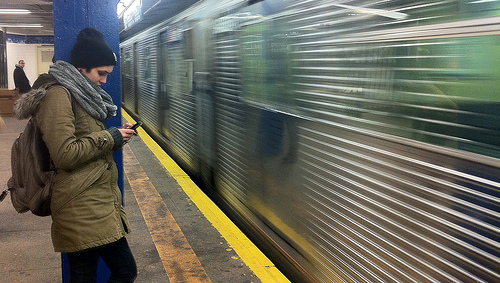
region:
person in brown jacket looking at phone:
[30, 23, 141, 279]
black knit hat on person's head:
[65, 25, 120, 67]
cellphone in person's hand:
[125, 115, 140, 130]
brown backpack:
[5, 120, 55, 216]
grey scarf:
[45, 60, 120, 120]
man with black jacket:
[10, 60, 30, 90]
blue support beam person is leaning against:
[50, 0, 115, 280]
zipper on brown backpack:
[0, 185, 10, 202]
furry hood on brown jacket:
[10, 72, 50, 117]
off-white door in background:
[35, 41, 55, 77]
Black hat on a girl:
[70, 26, 115, 66]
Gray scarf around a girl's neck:
[53, 72, 120, 109]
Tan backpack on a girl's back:
[6, 120, 58, 212]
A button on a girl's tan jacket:
[98, 136, 109, 144]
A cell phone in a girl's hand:
[129, 120, 141, 129]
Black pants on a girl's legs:
[64, 246, 138, 282]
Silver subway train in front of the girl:
[118, 11, 496, 281]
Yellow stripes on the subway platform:
[149, 175, 236, 278]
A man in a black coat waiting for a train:
[12, 56, 36, 93]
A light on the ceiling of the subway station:
[1, 4, 34, 18]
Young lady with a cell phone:
[15, 24, 150, 280]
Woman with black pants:
[7, 25, 156, 279]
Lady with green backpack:
[8, 24, 155, 281]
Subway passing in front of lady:
[123, 5, 499, 269]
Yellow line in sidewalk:
[121, 100, 274, 280]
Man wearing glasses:
[8, 52, 33, 97]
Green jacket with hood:
[13, 71, 133, 243]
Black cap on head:
[65, 23, 127, 65]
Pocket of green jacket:
[66, 161, 122, 223]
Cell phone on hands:
[113, 120, 147, 140]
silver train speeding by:
[299, 49, 484, 257]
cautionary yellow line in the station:
[139, 125, 278, 281]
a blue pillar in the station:
[54, 7, 119, 49]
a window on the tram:
[235, 27, 297, 120]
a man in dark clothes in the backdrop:
[12, 59, 30, 91]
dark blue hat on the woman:
[70, 35, 120, 65]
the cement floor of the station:
[3, 217, 52, 277]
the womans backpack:
[10, 115, 64, 207]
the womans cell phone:
[118, 122, 143, 132]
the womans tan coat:
[35, 84, 130, 241]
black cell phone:
[126, 114, 146, 131]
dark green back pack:
[6, 106, 65, 226]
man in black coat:
[13, 56, 38, 90]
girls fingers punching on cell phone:
[114, 122, 145, 147]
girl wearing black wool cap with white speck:
[69, 20, 125, 80]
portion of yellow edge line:
[170, 164, 197, 194]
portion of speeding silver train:
[175, 13, 497, 155]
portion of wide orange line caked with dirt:
[132, 179, 181, 233]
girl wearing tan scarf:
[49, 62, 121, 118]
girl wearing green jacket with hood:
[15, 78, 126, 254]